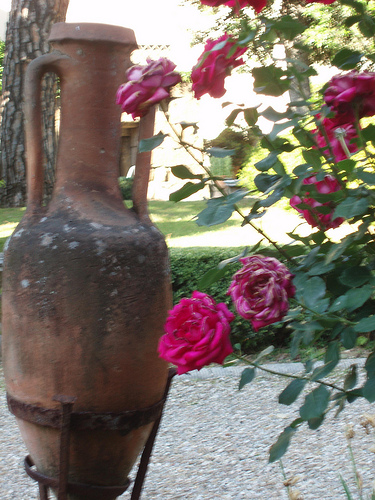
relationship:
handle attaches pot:
[11, 46, 61, 230] [0, 19, 174, 499]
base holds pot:
[16, 391, 186, 484] [22, 19, 202, 375]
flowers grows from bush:
[173, 9, 352, 358] [140, 237, 369, 367]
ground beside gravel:
[6, 186, 362, 492] [5, 338, 374, 498]